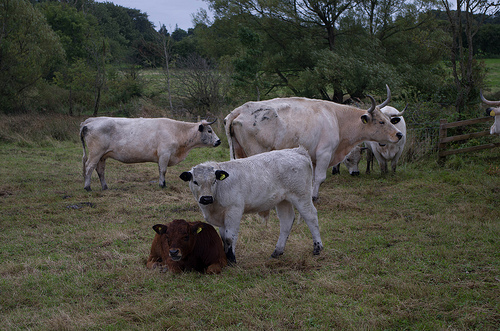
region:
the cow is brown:
[124, 202, 253, 294]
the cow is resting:
[142, 210, 225, 289]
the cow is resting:
[123, 207, 256, 310]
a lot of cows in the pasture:
[70, 79, 419, 280]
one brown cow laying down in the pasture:
[137, 221, 235, 276]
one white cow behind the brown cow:
[178, 144, 329, 261]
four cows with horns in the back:
[72, 83, 499, 196]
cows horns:
[362, 77, 392, 111]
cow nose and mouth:
[379, 126, 403, 146]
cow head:
[177, 165, 230, 205]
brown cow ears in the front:
[152, 223, 164, 234]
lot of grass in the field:
[2, 148, 490, 327]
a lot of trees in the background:
[2, 1, 494, 118]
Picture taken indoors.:
[17, 15, 499, 326]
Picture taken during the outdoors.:
[33, 17, 472, 118]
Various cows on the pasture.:
[66, 51, 456, 326]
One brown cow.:
[132, 208, 246, 275]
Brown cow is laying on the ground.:
[147, 210, 232, 283]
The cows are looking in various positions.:
[67, 64, 410, 282]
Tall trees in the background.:
[53, 18, 436, 70]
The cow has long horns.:
[352, 67, 397, 129]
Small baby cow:
[180, 158, 353, 233]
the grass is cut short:
[279, 224, 479, 302]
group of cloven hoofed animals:
[74, 83, 499, 278]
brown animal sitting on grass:
[136, 218, 229, 280]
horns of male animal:
[364, 81, 409, 121]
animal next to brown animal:
[144, 139, 332, 261]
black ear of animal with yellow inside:
[214, 169, 230, 181]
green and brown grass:
[4, 192, 144, 320]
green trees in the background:
[183, 0, 494, 100]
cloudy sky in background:
[132, 0, 219, 30]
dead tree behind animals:
[150, 27, 228, 119]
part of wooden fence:
[431, 111, 498, 166]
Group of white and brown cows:
[79, 82, 409, 277]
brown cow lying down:
[142, 215, 227, 274]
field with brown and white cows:
[3, 85, 498, 325]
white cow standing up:
[75, 113, 219, 192]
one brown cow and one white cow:
[142, 145, 322, 277]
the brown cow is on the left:
[141, 143, 323, 275]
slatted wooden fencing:
[434, 112, 496, 165]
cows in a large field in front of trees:
[3, 4, 496, 325]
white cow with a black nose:
[180, 143, 323, 266]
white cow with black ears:
[178, 143, 323, 276]